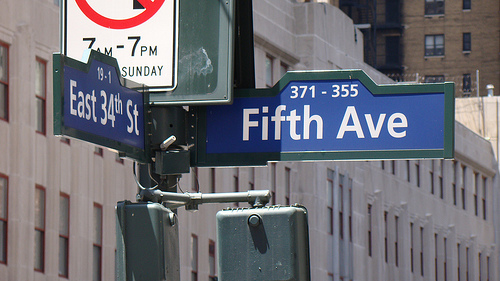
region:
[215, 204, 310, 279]
back of a do not walk sign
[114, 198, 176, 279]
back of a do not walk sign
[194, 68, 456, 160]
a blue and white street name sign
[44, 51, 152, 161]
a blue and white street name sign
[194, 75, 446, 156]
Fifth Ave street sign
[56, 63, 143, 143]
East 34th St street sign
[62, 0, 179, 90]
a no turn sign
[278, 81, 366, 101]
number range 371 - 355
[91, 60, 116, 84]
number range 19 - 1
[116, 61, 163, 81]
printed day Sunday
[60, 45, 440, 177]
blue and white street signs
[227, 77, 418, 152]
white text on blue background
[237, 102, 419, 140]
fifth ave in white on blue sign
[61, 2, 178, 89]
bottom of white, red, and black traffic sign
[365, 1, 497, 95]
brown building in the background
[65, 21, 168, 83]
black lettering on white background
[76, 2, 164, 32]
red circle on white background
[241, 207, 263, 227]
button on back of green box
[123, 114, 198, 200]
cords on green pole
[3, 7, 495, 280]
gray building behind signs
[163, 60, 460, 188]
the street sign is blue, black, and white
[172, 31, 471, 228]
the street sign says Fifth Ave in white letters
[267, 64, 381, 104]
the numbers on the sign are 371-355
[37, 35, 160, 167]
the street sign says East 34th St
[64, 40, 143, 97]
the numbers on the sign are 19-1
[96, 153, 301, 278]
the backs of two black don't walk boxes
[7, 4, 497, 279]
a tan building behind the signs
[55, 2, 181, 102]
red, black, and white no stopping sign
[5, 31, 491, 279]
lots of windows on the building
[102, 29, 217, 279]
pole holding street signs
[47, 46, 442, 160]
two blue street signs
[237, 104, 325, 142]
white print on a sign reading Fifth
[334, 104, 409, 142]
white print on a sign reading Ave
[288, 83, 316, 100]
white print on a sign reading 371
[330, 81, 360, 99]
white print on a sign reading 355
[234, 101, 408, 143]
white print on a blue street sign reading Fifth Ave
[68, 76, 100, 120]
white print on a blue street sign reading East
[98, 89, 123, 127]
white print on a blue street sign reading 34th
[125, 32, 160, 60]
black print on a street sign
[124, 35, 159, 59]
black print on a street sign reading 7PM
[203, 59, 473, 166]
blue with black frame sign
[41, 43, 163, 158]
blue with black frame sign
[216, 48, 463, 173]
street sign attached to post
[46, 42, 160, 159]
street sign attached to post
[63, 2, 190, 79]
traffic sign attached to post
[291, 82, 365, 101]
numeration on street sign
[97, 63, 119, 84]
numeration on street sign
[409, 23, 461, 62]
window on a building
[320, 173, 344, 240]
window on a building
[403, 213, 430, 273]
windows on a building